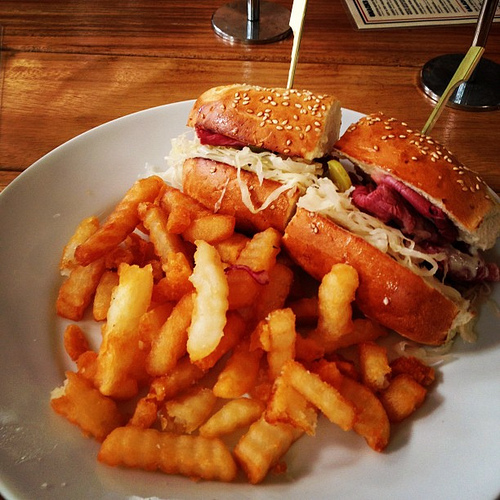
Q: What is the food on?
A: A plate.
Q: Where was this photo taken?
A: At a restaurant.